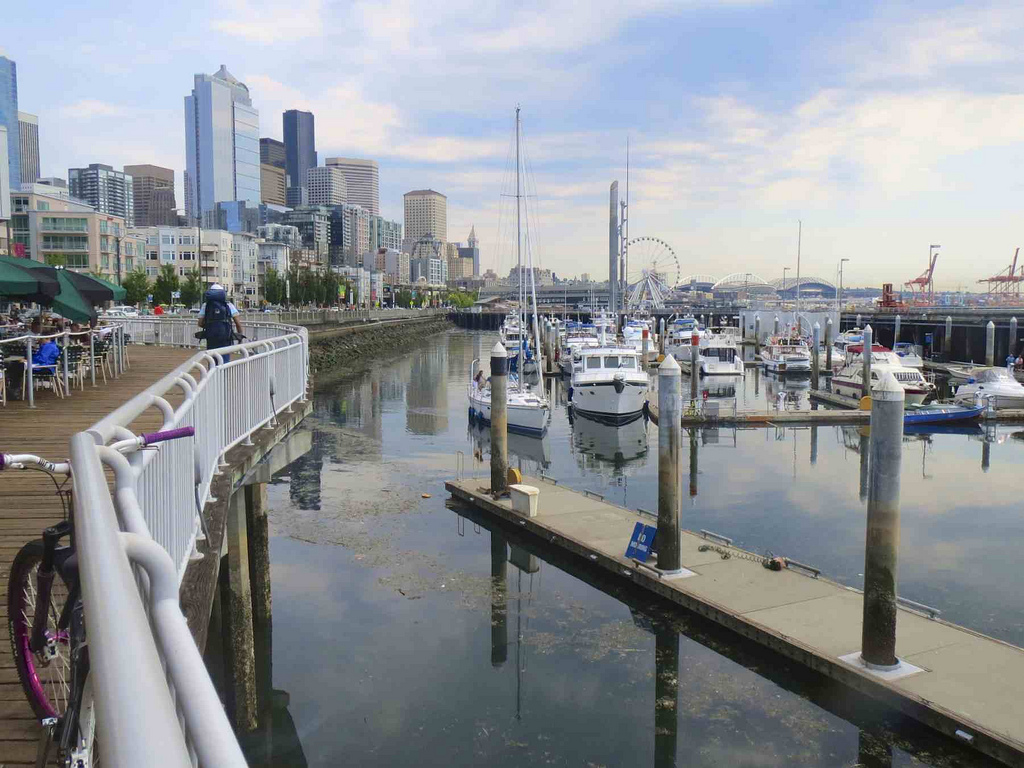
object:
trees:
[252, 258, 364, 312]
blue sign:
[621, 513, 660, 558]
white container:
[495, 475, 550, 523]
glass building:
[180, 61, 263, 235]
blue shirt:
[32, 327, 59, 367]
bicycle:
[28, 425, 97, 730]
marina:
[471, 284, 994, 753]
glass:
[205, 77, 255, 203]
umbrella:
[2, 245, 60, 310]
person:
[194, 279, 241, 340]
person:
[28, 327, 67, 373]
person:
[90, 318, 117, 338]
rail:
[65, 299, 344, 762]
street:
[230, 268, 443, 331]